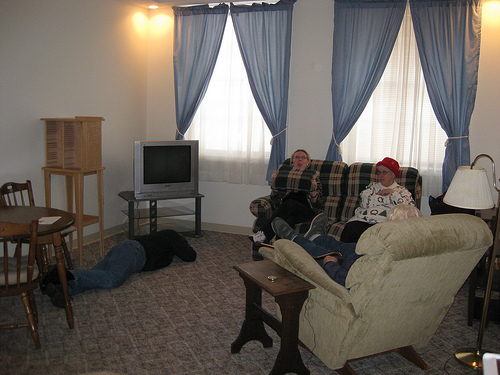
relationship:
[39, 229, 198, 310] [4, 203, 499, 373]
man lying on floor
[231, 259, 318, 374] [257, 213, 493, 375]
side table beside chair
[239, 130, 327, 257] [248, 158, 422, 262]
woman sitting on chair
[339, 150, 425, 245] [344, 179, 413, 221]
woman wearing sweater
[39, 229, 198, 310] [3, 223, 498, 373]
man on floor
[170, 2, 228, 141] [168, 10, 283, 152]
blue curtain on window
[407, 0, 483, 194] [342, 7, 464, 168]
blue curtain on window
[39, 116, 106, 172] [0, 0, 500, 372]
box in living room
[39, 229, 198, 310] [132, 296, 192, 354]
man laying in floor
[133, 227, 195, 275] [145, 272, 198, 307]
man laying in floor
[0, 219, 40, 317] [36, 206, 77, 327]
chair are around table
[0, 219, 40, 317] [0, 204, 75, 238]
chair are around table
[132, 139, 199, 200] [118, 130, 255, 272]
television on stand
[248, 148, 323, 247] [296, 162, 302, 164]
woman sticking out tongue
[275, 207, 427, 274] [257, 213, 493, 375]
person in chair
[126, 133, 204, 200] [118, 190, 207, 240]
television on a stand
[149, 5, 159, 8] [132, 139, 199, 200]
lamp in corner above television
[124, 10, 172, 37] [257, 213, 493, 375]
lamp behind chair